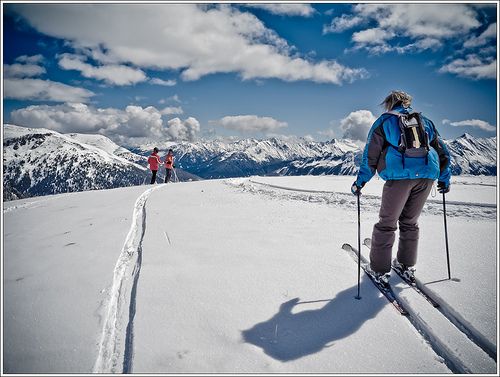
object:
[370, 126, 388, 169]
black color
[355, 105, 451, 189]
ski jacket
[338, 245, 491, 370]
tracks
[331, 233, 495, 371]
skis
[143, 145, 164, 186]
person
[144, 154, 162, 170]
jacket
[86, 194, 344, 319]
snow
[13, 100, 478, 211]
range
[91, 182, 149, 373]
long tracks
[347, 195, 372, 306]
ski pole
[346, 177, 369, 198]
skier's hand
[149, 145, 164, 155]
hat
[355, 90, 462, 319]
skier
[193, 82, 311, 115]
blue skies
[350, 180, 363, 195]
gloves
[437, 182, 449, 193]
gloves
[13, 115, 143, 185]
mountain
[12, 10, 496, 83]
white clouds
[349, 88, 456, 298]
woman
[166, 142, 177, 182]
woman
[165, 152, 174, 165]
jacket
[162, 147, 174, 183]
skier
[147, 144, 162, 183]
person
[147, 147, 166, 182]
skiers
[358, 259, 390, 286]
snow boot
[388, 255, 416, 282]
snow boot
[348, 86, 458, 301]
person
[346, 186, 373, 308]
pole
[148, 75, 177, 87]
cloud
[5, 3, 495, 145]
sky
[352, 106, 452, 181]
jacket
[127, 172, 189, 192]
skis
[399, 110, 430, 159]
backpack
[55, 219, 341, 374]
ground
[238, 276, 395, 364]
shadow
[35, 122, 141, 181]
hill